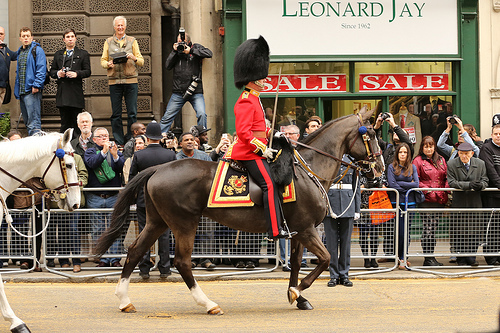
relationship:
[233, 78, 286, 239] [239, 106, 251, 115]
man wearing red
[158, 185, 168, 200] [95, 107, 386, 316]
brown colored horse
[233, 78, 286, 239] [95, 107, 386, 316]
man on horse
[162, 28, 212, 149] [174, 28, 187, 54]
person with camera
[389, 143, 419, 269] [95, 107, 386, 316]
person watching horse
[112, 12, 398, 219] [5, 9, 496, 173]
people in a city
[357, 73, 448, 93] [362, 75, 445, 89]
sign reads sale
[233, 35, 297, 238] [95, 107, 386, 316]
guard on horse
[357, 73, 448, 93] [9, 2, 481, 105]
sign on wall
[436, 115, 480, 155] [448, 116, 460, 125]
person has camera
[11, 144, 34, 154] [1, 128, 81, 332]
white colored horse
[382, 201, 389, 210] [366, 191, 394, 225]
orange colored bag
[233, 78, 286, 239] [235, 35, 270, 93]
officer has helmet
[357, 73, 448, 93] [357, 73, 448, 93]
sign has sign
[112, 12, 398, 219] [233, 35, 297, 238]
people see guard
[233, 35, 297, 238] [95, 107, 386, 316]
guard riding horse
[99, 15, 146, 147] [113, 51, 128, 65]
people taking photos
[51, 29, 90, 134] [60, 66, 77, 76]
man holding camera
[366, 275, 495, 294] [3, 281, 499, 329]
hay on street